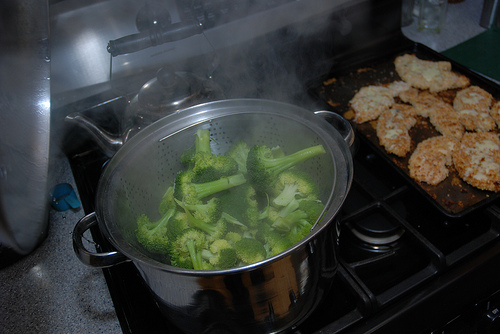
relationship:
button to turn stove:
[134, 1, 171, 36] [49, 0, 498, 332]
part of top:
[348, 267, 423, 310] [60, 20, 495, 332]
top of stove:
[60, 20, 495, 332] [49, 0, 498, 332]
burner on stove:
[347, 205, 405, 254] [47, 43, 477, 317]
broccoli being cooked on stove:
[141, 142, 334, 252] [49, 0, 498, 332]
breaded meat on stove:
[348, 53, 500, 191] [49, 0, 498, 332]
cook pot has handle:
[87, 75, 379, 309] [310, 102, 359, 149]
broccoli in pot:
[133, 128, 326, 270] [70, 99, 355, 331]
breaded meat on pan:
[348, 53, 500, 191] [304, 42, 500, 218]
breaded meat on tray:
[455, 130, 499, 184] [306, 29, 498, 220]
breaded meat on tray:
[348, 53, 500, 191] [306, 29, 498, 220]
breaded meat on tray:
[348, 53, 500, 191] [307, 36, 497, 269]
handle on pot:
[66, 208, 123, 269] [62, 90, 369, 330]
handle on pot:
[312, 110, 354, 147] [75, 93, 357, 318]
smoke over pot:
[95, 0, 322, 117] [70, 99, 355, 331]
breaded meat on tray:
[348, 53, 500, 191] [307, 42, 492, 240]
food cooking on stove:
[373, 52, 499, 190] [108, 56, 443, 327]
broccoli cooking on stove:
[133, 128, 326, 270] [108, 56, 443, 327]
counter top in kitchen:
[0, 151, 124, 332] [3, 3, 497, 331]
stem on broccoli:
[271, 141, 329, 168] [246, 137, 326, 194]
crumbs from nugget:
[437, 180, 472, 210] [454, 130, 498, 187]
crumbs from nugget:
[437, 180, 472, 210] [404, 130, 462, 185]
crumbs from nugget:
[437, 180, 472, 210] [393, 50, 467, 91]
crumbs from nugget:
[437, 180, 472, 210] [377, 101, 418, 158]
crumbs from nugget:
[437, 180, 472, 210] [348, 80, 403, 127]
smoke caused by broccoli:
[92, 12, 294, 189] [182, 140, 282, 244]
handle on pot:
[313, 87, 354, 195] [70, 99, 355, 331]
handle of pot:
[312, 110, 354, 147] [70, 99, 355, 331]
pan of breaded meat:
[303, 40, 483, 268] [348, 53, 500, 191]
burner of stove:
[352, 194, 424, 256] [47, 43, 477, 317]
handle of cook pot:
[72, 210, 132, 269] [72, 98, 356, 334]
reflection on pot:
[131, 259, 314, 314] [44, 78, 379, 317]